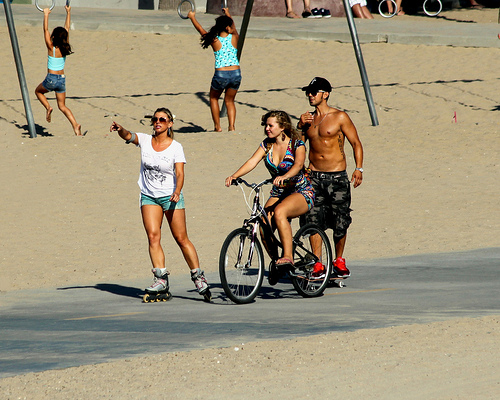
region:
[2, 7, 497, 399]
paved walkway passing through sandy areas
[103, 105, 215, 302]
woman on roller-blades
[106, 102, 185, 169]
woman pointing with her right hand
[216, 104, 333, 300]
a young woman riding a bicycle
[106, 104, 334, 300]
woman on bicycle looking toward woman on roller-blades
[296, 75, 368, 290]
shirtless man on a skateboard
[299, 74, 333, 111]
man wearing a black ball cap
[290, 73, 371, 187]
man's right hand is up near his face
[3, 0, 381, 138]
two women on metal rings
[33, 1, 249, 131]
two women wearing blue sleeveless tops and jean shorts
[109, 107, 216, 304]
young woman in skates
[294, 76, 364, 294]
man wearing black and red sneakers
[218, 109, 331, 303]
girl riding a black bike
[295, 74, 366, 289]
young man with silver watch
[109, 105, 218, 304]
girls wearing green shorts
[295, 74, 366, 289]
man with sunglasses and black hat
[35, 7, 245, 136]
two girl playing in the sand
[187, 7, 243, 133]
girl with long hair wearing shorts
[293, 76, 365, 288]
young man in the skateboard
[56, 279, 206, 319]
girl's shadow on the road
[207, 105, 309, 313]
a woman riding a bike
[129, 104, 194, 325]
a woman wearing roller skates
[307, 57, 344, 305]
a man riding a skateboard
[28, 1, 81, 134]
a young girl playing on park equipment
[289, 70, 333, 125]
a man wearing sunglasses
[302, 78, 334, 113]
a man wearing a black hat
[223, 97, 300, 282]
a woman riding a black bike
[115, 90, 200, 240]
a woman wearing a white shirt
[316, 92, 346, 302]
a man wearing black and red shoes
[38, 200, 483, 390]
a concrete sidewalk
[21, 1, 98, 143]
a girl hanging from metal rings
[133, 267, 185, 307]
roller blade skate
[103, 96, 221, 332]
a woman wearing shorts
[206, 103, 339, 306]
a woman wearing flip flops riding a bike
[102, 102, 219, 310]
a woman pointing at something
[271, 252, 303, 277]
a foot wearing flip flops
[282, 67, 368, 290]
a man riding a skateboard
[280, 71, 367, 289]
a man not wearing a shirt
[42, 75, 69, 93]
blue Levi's shorts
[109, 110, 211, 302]
A woman on roller skates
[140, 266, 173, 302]
A rollerskate on her right foot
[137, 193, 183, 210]
Woman is wearing blue shorts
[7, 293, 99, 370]
A path dividing the sand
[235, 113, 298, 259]
A woman on a bicycle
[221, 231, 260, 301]
The front tire of the bicycle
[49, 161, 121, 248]
Sand behind the skating woman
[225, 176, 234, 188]
The right hand of the woman on a bicycle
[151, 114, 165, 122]
Sunglasses on the skating woman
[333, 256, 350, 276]
A black shoe with red shoelaces